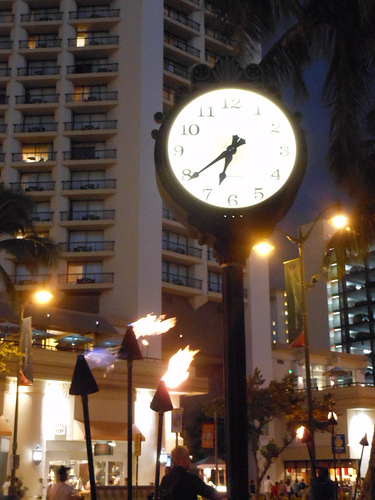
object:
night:
[0, 0, 375, 500]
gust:
[124, 314, 178, 346]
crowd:
[162, 454, 372, 499]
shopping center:
[0, 287, 369, 497]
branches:
[3, 190, 31, 233]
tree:
[0, 180, 45, 310]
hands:
[186, 132, 245, 184]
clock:
[154, 70, 311, 238]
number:
[181, 123, 199, 137]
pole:
[209, 239, 257, 499]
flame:
[128, 310, 177, 341]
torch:
[116, 326, 143, 500]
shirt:
[156, 467, 221, 500]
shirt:
[41, 480, 84, 500]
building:
[1, 3, 271, 488]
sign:
[329, 434, 347, 455]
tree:
[0, 179, 64, 500]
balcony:
[71, 85, 121, 109]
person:
[158, 447, 226, 500]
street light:
[318, 196, 349, 231]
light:
[75, 34, 85, 47]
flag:
[281, 252, 310, 351]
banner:
[200, 424, 216, 449]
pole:
[213, 411, 221, 495]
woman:
[44, 462, 88, 500]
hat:
[49, 464, 74, 472]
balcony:
[8, 149, 63, 169]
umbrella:
[57, 329, 91, 345]